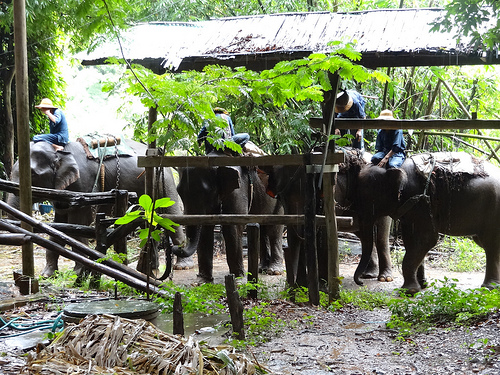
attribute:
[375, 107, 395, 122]
hat — straw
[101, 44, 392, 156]
plants — green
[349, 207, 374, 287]
trunk — elephant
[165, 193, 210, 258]
trunk — elephant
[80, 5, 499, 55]
roof — thatch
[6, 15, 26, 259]
pole — wooden 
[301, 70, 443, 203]
workers — farm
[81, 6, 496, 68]
roof — thatch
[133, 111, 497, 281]
fencing — wooden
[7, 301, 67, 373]
hose — green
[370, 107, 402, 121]
hat — straw 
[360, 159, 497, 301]
elephant — herd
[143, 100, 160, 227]
post — wooden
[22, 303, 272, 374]
haystack — brown